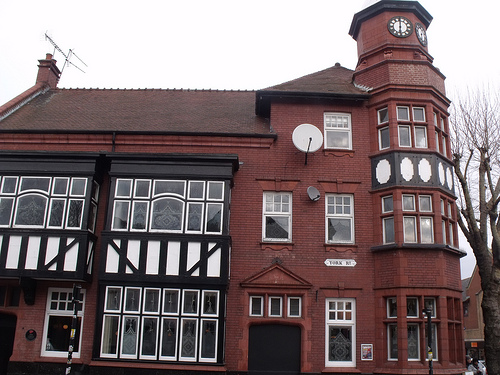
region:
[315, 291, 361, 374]
Door to a building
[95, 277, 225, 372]
Windows of a building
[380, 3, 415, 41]
Clock on a building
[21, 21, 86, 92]
Antennas on a building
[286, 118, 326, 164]
Satellite dish on a building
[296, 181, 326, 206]
Satellite dish attached to a building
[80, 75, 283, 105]
Top of a building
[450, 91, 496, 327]
Tree next to a building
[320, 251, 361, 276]
Sign on a building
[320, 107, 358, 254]
Two windows of a building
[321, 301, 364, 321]
six windows in one window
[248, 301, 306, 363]
three windows above the door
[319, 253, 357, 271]
sign on the building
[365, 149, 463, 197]
decorative design on building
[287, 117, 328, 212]
two satelite dishes on the building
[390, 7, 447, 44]
clocks on the top of building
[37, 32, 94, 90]
power line on top of building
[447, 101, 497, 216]
tree does not have leaves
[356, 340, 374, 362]
sign on the building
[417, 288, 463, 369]
light pole on side of building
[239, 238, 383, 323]
The building is made out of brick.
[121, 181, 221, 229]
The windows are stained with white decor.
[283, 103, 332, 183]
A satellite disk on the building.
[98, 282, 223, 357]
The building has windows.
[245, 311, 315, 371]
The door of the building.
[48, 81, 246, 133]
The rooftop is brown.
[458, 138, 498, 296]
The tree is bare.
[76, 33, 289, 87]
The sky is cloudy.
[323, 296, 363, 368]
The window is trimmed in white.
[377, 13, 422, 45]
A clock is on top of the building.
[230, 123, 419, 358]
House is made of red brick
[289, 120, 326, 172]
House has a white dish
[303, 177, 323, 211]
House has a small grey dish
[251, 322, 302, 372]
House has a black door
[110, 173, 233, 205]
House has a row of windows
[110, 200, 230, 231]
House has a row of windows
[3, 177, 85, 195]
House has a row of windows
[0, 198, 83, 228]
House has a row of windows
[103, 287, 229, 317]
House has a row windows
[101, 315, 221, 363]
House has a row of windows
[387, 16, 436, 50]
TWO CLOCKS ON TOP OF A BUILDING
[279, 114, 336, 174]
A SATELLITE DISH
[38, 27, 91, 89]
A ANTENNA ON THE ROOF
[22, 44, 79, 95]
A BRICK CHIMNEY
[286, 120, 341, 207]
TWO SATELLITE DISHES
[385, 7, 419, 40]
A CLOCK DISPLAYING 6:00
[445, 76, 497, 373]
A TREE WITH NO LEAVES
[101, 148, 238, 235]
A WINDOW WITH A BLACK LEDGE ON TOP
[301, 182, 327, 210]
A SMALL GRAY SATELLITE DISH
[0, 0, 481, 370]
A PICTURE OF A BRICK BUILDING